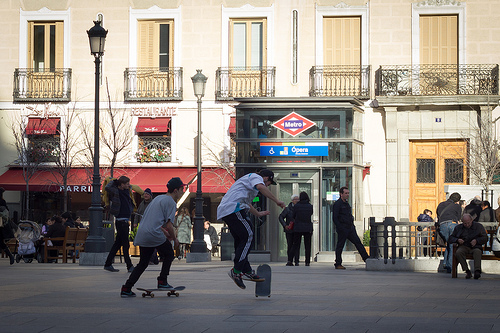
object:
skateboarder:
[229, 167, 291, 210]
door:
[280, 170, 319, 188]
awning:
[2, 161, 239, 196]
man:
[121, 177, 185, 295]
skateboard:
[136, 283, 188, 300]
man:
[452, 211, 491, 284]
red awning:
[7, 155, 245, 211]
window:
[19, 112, 69, 161]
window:
[128, 110, 175, 163]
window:
[11, 9, 72, 101]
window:
[119, 2, 188, 104]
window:
[212, 0, 275, 99]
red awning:
[17, 107, 70, 142]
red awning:
[129, 109, 181, 144]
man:
[442, 211, 491, 286]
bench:
[430, 219, 499, 273]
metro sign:
[283, 120, 303, 128]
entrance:
[270, 170, 324, 269]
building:
[0, 1, 498, 261]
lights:
[79, 19, 223, 136]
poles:
[77, 125, 209, 182]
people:
[278, 186, 317, 269]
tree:
[450, 111, 494, 180]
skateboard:
[253, 259, 274, 304]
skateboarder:
[214, 166, 286, 293]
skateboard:
[254, 262, 271, 298]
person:
[281, 191, 304, 265]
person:
[294, 191, 314, 270]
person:
[331, 187, 370, 269]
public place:
[3, 170, 498, 329]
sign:
[257, 138, 331, 162]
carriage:
[15, 219, 52, 263]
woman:
[38, 210, 79, 258]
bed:
[265, 141, 277, 159]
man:
[449, 209, 486, 281]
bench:
[437, 221, 498, 277]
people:
[27, 207, 90, 258]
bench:
[37, 225, 94, 262]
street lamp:
[65, 17, 122, 275]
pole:
[90, 53, 100, 252]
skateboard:
[130, 282, 187, 299]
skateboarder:
[115, 176, 187, 302]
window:
[138, 17, 179, 98]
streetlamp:
[179, 71, 229, 269]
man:
[330, 185, 370, 269]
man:
[115, 174, 187, 300]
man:
[100, 172, 140, 273]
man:
[215, 172, 286, 289]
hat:
[167, 177, 190, 190]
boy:
[120, 174, 185, 297]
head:
[166, 179, 185, 202]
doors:
[390, 114, 471, 259]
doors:
[408, 138, 473, 255]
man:
[106, 162, 197, 292]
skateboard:
[139, 279, 185, 300]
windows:
[0, 0, 379, 97]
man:
[444, 199, 494, 281]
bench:
[440, 222, 499, 250]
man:
[412, 179, 467, 289]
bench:
[373, 185, 489, 279]